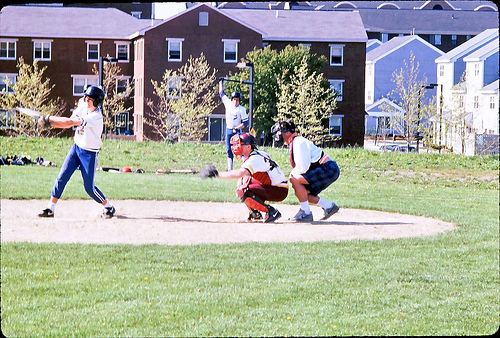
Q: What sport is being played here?
A: Baseball.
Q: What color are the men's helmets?
A: Black.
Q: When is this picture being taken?
A: Daytime.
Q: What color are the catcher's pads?
A: Red.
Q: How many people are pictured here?
A: Four.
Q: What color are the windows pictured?
A: White.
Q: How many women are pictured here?
A: Zero.